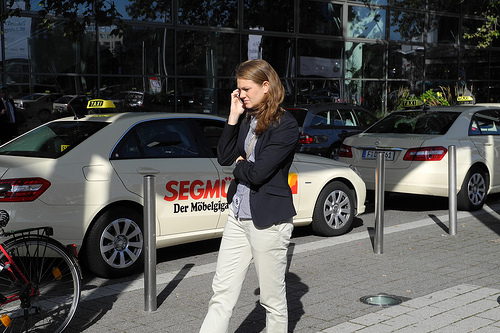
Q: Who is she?
A: A pedestrian.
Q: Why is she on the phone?
A: Talking.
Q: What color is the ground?
A: Grey.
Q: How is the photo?
A: Clear.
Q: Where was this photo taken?
A: City sidewalk.